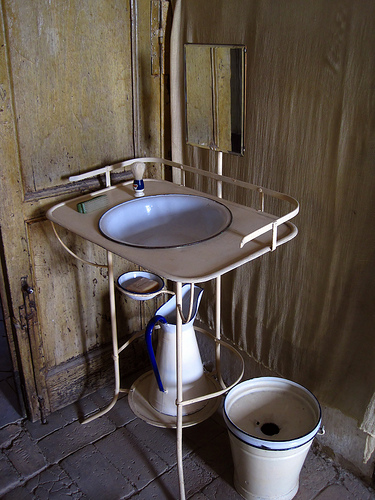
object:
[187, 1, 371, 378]
wall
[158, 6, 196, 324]
corner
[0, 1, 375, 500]
room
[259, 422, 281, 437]
hole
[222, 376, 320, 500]
bucket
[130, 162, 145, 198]
faucet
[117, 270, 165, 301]
soap dish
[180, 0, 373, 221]
area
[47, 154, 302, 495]
stand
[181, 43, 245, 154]
mirror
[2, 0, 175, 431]
wall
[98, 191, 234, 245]
sink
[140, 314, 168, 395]
handle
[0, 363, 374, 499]
floor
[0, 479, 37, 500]
brick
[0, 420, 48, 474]
brick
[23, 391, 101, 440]
brick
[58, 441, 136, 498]
brick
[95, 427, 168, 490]
brick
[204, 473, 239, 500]
brick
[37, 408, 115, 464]
brick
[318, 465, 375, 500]
brick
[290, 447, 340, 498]
brick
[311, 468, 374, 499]
brick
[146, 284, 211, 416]
pitcher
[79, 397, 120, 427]
support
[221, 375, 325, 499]
pail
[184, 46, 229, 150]
wall